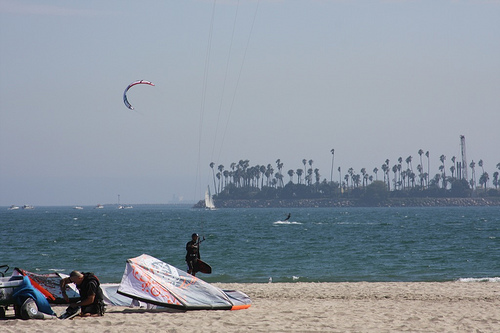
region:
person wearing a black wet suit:
[177, 232, 210, 272]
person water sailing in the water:
[270, 205, 305, 227]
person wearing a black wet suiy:
[183, 239, 210, 279]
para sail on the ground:
[86, 239, 261, 326]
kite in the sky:
[103, 66, 165, 124]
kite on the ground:
[14, 263, 56, 317]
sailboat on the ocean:
[201, 176, 215, 211]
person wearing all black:
[172, 216, 231, 283]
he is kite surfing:
[104, 51, 334, 239]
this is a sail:
[107, 242, 242, 328]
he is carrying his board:
[175, 191, 230, 285]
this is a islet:
[178, 133, 498, 215]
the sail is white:
[191, 178, 223, 218]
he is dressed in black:
[165, 203, 245, 298]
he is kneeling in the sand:
[53, 255, 126, 331]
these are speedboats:
[6, 193, 154, 225]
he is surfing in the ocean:
[256, 202, 323, 227]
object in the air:
[88, 41, 203, 144]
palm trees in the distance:
[186, 134, 417, 221]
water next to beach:
[260, 204, 381, 283]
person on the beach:
[32, 257, 116, 332]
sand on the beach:
[271, 270, 349, 331]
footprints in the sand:
[248, 291, 345, 332]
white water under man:
[259, 212, 300, 234]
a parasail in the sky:
[71, 47, 183, 133]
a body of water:
[204, 195, 441, 318]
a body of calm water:
[298, 201, 475, 295]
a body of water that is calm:
[323, 214, 495, 292]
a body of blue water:
[241, 193, 417, 298]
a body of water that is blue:
[224, 214, 436, 328]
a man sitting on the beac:
[41, 243, 121, 327]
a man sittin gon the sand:
[39, 266, 112, 325]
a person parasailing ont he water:
[37, 29, 364, 243]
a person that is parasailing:
[72, 48, 381, 303]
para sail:
[100, 73, 174, 128]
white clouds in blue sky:
[238, 65, 283, 102]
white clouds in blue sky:
[365, 19, 403, 46]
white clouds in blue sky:
[300, 22, 343, 52]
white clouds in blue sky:
[467, 35, 477, 51]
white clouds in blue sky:
[317, 52, 410, 82]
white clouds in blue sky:
[291, 88, 346, 153]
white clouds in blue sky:
[35, 110, 65, 130]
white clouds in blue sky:
[291, 95, 318, 118]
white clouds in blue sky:
[212, 21, 270, 65]